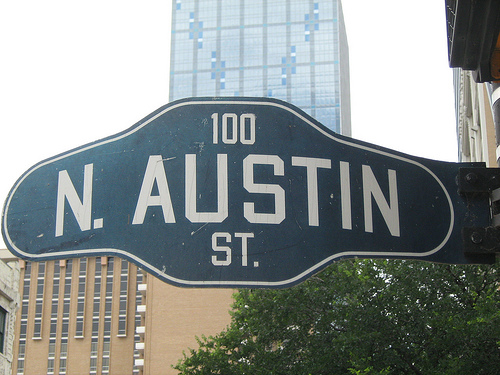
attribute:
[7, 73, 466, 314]
sign — here, lettered, black, white, bolted, numbered, held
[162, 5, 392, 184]
building — tall, brick, brown, glass, multistory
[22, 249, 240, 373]
building — brown, concrete, redn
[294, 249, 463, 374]
tree — green, leafy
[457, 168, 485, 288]
bolt — black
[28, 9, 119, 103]
sky — gray, cloudy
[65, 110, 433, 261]
letter — white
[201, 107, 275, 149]
number — white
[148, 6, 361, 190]
skyscraper — here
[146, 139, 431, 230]
text — white, bold